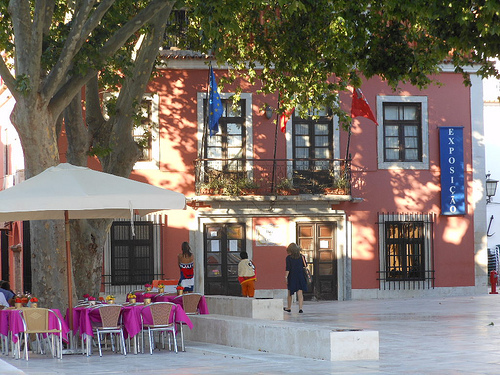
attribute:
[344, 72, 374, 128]
flag — red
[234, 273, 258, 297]
pants — orange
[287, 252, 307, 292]
dress — blue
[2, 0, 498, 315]
tree — big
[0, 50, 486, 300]
building — big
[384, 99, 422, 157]
window — glass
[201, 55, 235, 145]
flag — blue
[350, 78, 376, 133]
flag — red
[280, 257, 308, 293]
dress — black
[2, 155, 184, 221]
umbrella — tan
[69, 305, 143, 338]
tablecloth — bright pink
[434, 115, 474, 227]
sign — blue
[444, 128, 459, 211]
letters — white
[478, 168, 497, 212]
lantern — wall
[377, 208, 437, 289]
cage — metal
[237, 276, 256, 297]
pants — red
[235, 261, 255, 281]
shirt — tan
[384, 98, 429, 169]
window — brown, wood framed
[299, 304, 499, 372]
walkway — grey, cement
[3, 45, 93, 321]
trunk — brown, tree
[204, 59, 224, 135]
flag — blue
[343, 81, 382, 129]
flag — red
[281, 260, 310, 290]
dress — blue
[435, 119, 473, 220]
sign — blue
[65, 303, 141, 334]
tablecloth — purple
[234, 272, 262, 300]
pants — orange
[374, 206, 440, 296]
gate — metal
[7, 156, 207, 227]
umbrella — big, white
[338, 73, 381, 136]
flag — red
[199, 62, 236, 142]
flag — blue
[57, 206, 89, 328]
pole — brown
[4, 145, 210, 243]
umbrella — large, white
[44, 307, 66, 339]
cloth — purple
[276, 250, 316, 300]
dress — black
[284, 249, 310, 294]
dress — maxi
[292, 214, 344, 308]
front door — large, brown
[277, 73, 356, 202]
window — large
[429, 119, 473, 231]
sign — large, blue and white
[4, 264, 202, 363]
outdoor — arrangement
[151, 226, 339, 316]
woman — three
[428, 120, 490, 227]
signboard — blue, white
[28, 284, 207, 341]
chair — pink, arranged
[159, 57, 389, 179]
flags — mounted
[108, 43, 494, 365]
building — brown, painted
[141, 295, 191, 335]
chair — brown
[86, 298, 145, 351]
chair — brown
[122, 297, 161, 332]
tablecloth — bright pink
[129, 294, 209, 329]
tablecloth — bright pink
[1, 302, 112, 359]
tablecloth — bright pink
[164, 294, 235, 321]
tablecloth — bright pink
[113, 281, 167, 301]
tablecloth — bright pink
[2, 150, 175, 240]
umbrella — oversized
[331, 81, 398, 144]
flag — red, waving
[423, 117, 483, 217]
banner — blue, long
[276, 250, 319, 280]
dress — blue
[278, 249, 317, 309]
lady — walking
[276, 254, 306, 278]
dress — blue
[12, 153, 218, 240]
umbrella — white, large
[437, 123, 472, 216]
banner — blue and white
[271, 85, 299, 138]
flag — red